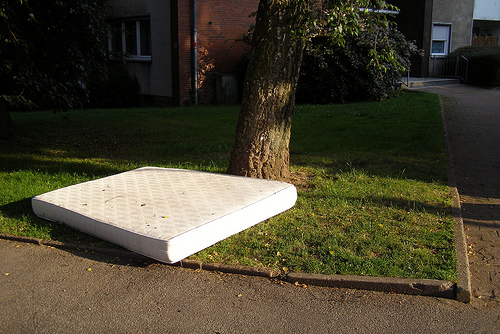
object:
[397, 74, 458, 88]
puddle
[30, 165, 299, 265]
mattress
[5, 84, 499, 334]
ground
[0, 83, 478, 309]
curb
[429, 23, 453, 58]
white window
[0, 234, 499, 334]
sidewalk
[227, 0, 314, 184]
bark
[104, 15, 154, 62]
window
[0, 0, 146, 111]
bush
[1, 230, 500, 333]
road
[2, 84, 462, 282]
grass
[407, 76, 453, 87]
step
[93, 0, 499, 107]
building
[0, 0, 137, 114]
tree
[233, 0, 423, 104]
bush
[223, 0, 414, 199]
tree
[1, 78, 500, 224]
shadows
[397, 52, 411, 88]
rail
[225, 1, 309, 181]
trunk